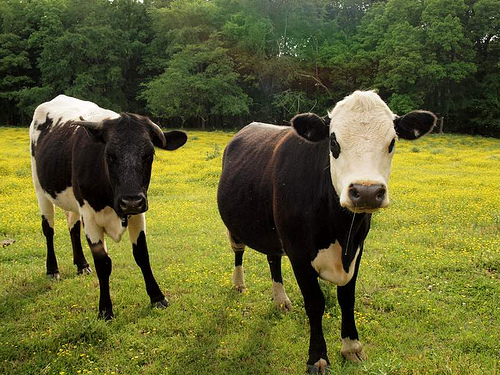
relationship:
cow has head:
[215, 81, 435, 373] [291, 90, 437, 214]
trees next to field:
[132, 14, 499, 159] [2, 125, 498, 373]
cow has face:
[215, 81, 435, 373] [326, 90, 390, 199]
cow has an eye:
[215, 81, 435, 373] [328, 131, 341, 158]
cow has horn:
[25, 90, 190, 318] [141, 110, 168, 150]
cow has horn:
[25, 90, 190, 318] [62, 115, 106, 129]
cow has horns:
[25, 90, 190, 318] [75, 117, 171, 153]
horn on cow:
[140, 111, 185, 151] [215, 81, 435, 373]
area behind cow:
[2, 5, 497, 132] [215, 81, 435, 373]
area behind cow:
[2, 5, 497, 132] [29, 86, 166, 331]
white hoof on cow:
[269, 292, 294, 312] [215, 81, 435, 373]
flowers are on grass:
[1, 135, 491, 284] [1, 122, 498, 374]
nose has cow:
[338, 175, 398, 218] [215, 81, 435, 373]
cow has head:
[30, 92, 190, 319] [82, 117, 175, 223]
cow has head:
[25, 90, 190, 318] [76, 109, 181, 229]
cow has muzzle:
[30, 92, 190, 319] [103, 196, 160, 226]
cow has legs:
[215, 81, 435, 373] [295, 252, 363, 372]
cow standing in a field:
[30, 92, 190, 319] [2, 125, 498, 373]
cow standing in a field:
[215, 81, 435, 373] [2, 125, 498, 373]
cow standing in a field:
[30, 92, 190, 319] [4, 89, 494, 368]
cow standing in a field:
[215, 81, 435, 373] [4, 89, 494, 368]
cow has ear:
[215, 81, 435, 373] [405, 113, 441, 147]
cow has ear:
[215, 81, 435, 373] [156, 125, 196, 159]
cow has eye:
[215, 81, 435, 373] [385, 140, 397, 150]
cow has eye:
[30, 92, 190, 319] [104, 151, 119, 166]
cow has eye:
[215, 81, 435, 373] [104, 151, 119, 166]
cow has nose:
[215, 81, 435, 373] [347, 180, 387, 208]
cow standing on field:
[25, 90, 190, 318] [2, 125, 498, 373]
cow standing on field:
[215, 81, 435, 373] [2, 125, 498, 373]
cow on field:
[25, 90, 190, 318] [6, 120, 498, 329]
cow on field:
[215, 81, 435, 373] [6, 120, 498, 329]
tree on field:
[362, 5, 491, 104] [399, 140, 499, 367]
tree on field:
[248, 4, 362, 106] [399, 140, 499, 367]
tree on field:
[153, 5, 249, 120] [160, 144, 232, 371]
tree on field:
[5, 5, 115, 101] [0, 273, 87, 369]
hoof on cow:
[146, 293, 171, 310] [25, 83, 202, 349]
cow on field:
[215, 81, 435, 373] [2, 125, 498, 373]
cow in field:
[25, 90, 190, 318] [5, 275, 499, 370]